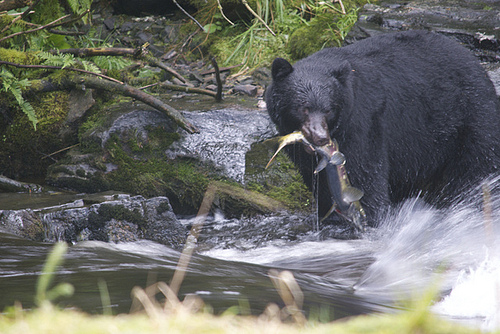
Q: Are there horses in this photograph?
A: No, there are no horses.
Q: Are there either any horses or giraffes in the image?
A: No, there are no horses or giraffes.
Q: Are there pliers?
A: No, there are no pliers.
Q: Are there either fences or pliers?
A: No, there are no pliers or fences.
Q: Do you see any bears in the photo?
A: Yes, there is a bear.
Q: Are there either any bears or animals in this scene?
A: Yes, there is a bear.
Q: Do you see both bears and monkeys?
A: No, there is a bear but no monkeys.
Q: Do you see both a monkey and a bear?
A: No, there is a bear but no monkeys.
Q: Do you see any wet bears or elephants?
A: Yes, there is a wet bear.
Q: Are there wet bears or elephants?
A: Yes, there is a wet bear.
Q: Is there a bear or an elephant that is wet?
A: Yes, the bear is wet.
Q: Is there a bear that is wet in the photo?
A: Yes, there is a wet bear.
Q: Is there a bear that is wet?
A: Yes, there is a bear that is wet.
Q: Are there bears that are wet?
A: Yes, there is a bear that is wet.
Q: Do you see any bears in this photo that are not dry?
A: Yes, there is a wet bear.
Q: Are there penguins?
A: No, there are no penguins.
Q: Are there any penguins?
A: No, there are no penguins.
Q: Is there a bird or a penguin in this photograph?
A: No, there are no penguins or birds.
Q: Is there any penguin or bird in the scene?
A: No, there are no penguins or birds.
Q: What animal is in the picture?
A: The animal is a bear.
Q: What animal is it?
A: The animal is a bear.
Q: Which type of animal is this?
A: This is a bear.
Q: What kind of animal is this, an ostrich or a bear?
A: This is a bear.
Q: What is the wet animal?
A: The animal is a bear.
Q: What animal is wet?
A: The animal is a bear.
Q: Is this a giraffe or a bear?
A: This is a bear.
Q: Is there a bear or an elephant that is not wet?
A: No, there is a bear but it is wet.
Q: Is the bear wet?
A: Yes, the bear is wet.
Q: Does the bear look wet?
A: Yes, the bear is wet.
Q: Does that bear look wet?
A: Yes, the bear is wet.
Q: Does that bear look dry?
A: No, the bear is wet.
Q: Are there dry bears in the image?
A: No, there is a bear but it is wet.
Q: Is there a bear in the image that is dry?
A: No, there is a bear but it is wet.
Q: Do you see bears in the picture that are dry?
A: No, there is a bear but it is wet.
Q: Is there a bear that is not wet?
A: No, there is a bear but it is wet.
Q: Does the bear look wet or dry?
A: The bear is wet.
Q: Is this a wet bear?
A: Yes, this is a wet bear.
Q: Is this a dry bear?
A: No, this is a wet bear.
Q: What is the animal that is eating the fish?
A: The animal is a bear.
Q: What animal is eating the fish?
A: The animal is a bear.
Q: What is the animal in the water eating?
A: The bear is eating fish.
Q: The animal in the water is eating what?
A: The bear is eating fish.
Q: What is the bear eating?
A: The bear is eating fish.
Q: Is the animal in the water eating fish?
A: Yes, the bear is eating fish.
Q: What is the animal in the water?
A: The animal is a bear.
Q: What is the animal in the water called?
A: The animal is a bear.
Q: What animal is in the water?
A: The animal is a bear.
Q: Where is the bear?
A: The bear is in the water.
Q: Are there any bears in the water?
A: Yes, there is a bear in the water.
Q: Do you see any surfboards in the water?
A: No, there is a bear in the water.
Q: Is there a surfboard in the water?
A: No, there is a bear in the water.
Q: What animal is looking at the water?
A: The bear is looking at the water.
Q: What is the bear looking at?
A: The bear is looking at the water.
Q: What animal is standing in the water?
A: The animal is a bear.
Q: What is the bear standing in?
A: The bear is standing in the water.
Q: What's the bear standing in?
A: The bear is standing in the water.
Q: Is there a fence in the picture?
A: No, there are no fences.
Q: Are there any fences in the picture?
A: No, there are no fences.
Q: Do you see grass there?
A: Yes, there is grass.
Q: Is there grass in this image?
A: Yes, there is grass.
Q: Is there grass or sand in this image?
A: Yes, there is grass.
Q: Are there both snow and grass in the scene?
A: No, there is grass but no snow.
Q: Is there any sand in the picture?
A: No, there is no sand.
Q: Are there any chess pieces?
A: No, there are no chess pieces.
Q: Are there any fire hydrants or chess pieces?
A: No, there are no chess pieces or fire hydrants.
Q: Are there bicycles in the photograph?
A: No, there are no bicycles.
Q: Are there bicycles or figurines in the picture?
A: No, there are no bicycles or figurines.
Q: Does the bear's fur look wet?
A: Yes, the fur is wet.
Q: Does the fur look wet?
A: Yes, the fur is wet.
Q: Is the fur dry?
A: No, the fur is wet.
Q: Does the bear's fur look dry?
A: No, the fur is wet.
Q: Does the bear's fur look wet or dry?
A: The fur is wet.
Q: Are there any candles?
A: No, there are no candles.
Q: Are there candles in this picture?
A: No, there are no candles.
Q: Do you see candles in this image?
A: No, there are no candles.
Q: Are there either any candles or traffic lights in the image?
A: No, there are no candles or traffic lights.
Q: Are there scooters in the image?
A: No, there are no scooters.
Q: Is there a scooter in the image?
A: No, there are no scooters.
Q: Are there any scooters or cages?
A: No, there are no scooters or cages.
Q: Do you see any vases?
A: No, there are no vases.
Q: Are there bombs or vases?
A: No, there are no vases or bombs.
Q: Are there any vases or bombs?
A: No, there are no vases or bombs.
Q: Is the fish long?
A: Yes, the fish is long.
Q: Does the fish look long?
A: Yes, the fish is long.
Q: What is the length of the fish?
A: The fish is long.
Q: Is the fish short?
A: No, the fish is long.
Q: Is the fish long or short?
A: The fish is long.